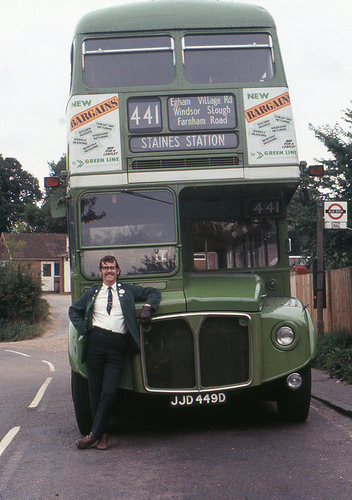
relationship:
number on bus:
[124, 98, 167, 132] [60, 4, 325, 438]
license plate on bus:
[166, 388, 233, 409] [60, 4, 325, 438]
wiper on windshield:
[112, 185, 179, 210] [74, 187, 183, 279]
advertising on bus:
[65, 89, 120, 183] [60, 4, 325, 438]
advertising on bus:
[243, 83, 305, 167] [60, 4, 325, 438]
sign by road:
[315, 192, 348, 321] [2, 340, 350, 500]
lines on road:
[0, 344, 59, 471] [2, 340, 350, 500]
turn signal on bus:
[38, 173, 72, 196] [60, 4, 325, 438]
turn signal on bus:
[304, 162, 333, 187] [60, 4, 325, 438]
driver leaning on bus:
[64, 254, 163, 459] [60, 4, 325, 438]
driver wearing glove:
[64, 254, 163, 459] [133, 301, 162, 331]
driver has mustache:
[64, 254, 163, 459] [103, 267, 121, 279]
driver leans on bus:
[64, 254, 163, 459] [60, 4, 325, 438]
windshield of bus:
[74, 187, 183, 279] [60, 4, 325, 438]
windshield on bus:
[79, 35, 287, 90] [60, 4, 325, 438]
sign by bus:
[315, 192, 348, 321] [60, 4, 325, 438]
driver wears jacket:
[64, 254, 163, 459] [68, 282, 164, 351]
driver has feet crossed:
[64, 254, 163, 459] [70, 424, 120, 461]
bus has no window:
[60, 4, 325, 438] [174, 178, 299, 279]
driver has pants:
[64, 254, 163, 459] [79, 324, 126, 442]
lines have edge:
[0, 344, 59, 471] [37, 374, 56, 407]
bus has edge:
[60, 4, 325, 438] [65, 38, 86, 459]